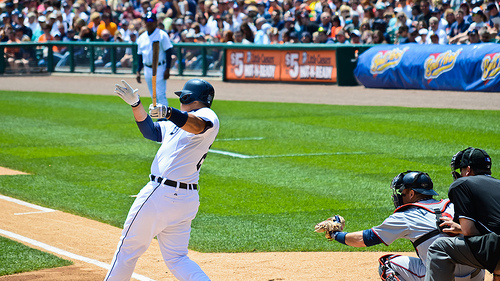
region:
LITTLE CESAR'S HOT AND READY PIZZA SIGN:
[226, 48, 334, 78]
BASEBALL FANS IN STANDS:
[278, 9, 490, 41]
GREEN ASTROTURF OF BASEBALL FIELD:
[258, 130, 390, 171]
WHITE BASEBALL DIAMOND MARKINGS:
[0, 190, 57, 265]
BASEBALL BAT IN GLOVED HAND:
[146, 38, 163, 123]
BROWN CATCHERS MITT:
[313, 212, 349, 244]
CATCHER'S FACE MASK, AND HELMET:
[391, 168, 433, 210]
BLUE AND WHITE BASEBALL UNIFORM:
[136, 108, 212, 279]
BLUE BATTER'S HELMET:
[171, 79, 218, 110]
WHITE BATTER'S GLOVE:
[114, 80, 142, 107]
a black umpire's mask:
[432, 140, 499, 182]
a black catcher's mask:
[372, 161, 437, 210]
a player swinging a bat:
[89, 31, 228, 278]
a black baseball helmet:
[163, 72, 231, 118]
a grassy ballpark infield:
[3, 80, 494, 276]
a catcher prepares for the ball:
[297, 163, 476, 277]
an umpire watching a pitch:
[421, 135, 498, 280]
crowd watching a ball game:
[1, 4, 495, 112]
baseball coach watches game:
[119, 10, 187, 110]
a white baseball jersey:
[95, 103, 242, 188]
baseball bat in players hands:
[141, 37, 168, 104]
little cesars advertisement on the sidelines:
[222, 49, 339, 84]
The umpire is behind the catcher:
[421, 140, 497, 279]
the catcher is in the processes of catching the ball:
[304, 164, 461, 279]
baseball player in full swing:
[101, 38, 226, 278]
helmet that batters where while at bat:
[177, 80, 217, 104]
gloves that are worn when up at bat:
[112, 78, 142, 107]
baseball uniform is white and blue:
[107, 109, 240, 279]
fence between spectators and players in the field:
[1, 40, 361, 85]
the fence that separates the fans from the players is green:
[3, 40, 356, 84]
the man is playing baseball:
[97, 80, 221, 276]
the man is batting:
[98, 76, 218, 279]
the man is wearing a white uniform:
[105, 82, 217, 278]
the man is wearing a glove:
[116, 80, 141, 107]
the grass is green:
[0, 93, 498, 277]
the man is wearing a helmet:
[176, 80, 216, 102]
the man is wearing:
[136, 13, 172, 105]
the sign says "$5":
[220, 46, 335, 83]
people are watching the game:
[4, 0, 494, 67]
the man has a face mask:
[390, 180, 405, 208]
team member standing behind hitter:
[98, 10, 254, 150]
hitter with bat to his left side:
[55, 27, 265, 263]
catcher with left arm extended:
[305, 152, 440, 277]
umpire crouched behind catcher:
[422, 111, 492, 276]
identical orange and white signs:
[220, 20, 340, 87]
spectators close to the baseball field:
[25, 2, 480, 37]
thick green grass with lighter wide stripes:
[217, 100, 393, 245]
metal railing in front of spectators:
[10, 30, 241, 77]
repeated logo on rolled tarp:
[345, 25, 496, 100]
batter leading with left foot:
[81, 40, 226, 271]